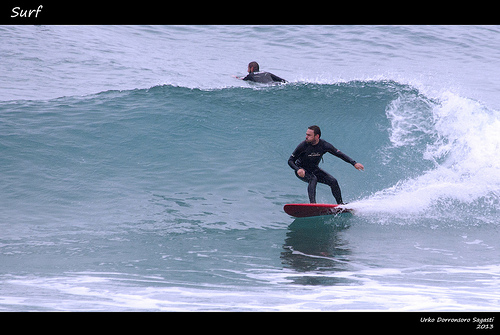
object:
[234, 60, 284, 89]
guy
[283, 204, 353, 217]
board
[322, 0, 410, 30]
sky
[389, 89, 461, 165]
white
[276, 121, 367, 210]
suit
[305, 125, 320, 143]
man head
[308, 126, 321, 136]
wet hair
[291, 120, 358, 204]
guy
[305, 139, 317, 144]
beard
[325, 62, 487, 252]
wave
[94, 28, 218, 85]
clouds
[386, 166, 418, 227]
ground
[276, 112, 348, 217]
man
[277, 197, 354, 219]
surfboard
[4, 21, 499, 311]
water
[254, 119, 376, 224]
person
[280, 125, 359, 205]
man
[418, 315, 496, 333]
logo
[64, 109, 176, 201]
orange shirt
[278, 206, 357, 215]
surfboard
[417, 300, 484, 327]
corner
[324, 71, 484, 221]
foam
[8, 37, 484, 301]
ocean